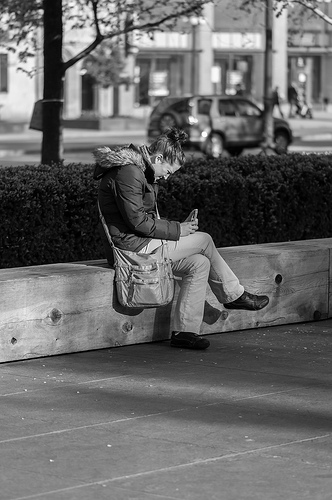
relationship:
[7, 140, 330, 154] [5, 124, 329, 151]
road has tarmac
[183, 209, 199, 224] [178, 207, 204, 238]
cake on top of plate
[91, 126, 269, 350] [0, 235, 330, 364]
lady sitting on plank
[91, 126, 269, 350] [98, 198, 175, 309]
lady with bag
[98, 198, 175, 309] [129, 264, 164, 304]
bag with pocket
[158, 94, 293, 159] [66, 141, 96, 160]
car driving down street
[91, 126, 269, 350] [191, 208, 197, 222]
lady looking at cell phone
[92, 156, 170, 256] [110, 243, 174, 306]
strap on bag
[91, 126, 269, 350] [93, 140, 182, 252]
lady with coat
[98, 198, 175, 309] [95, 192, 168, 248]
bag has strap